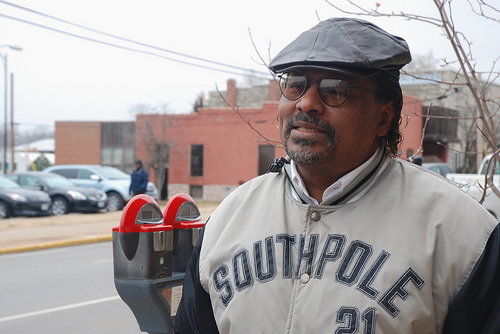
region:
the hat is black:
[265, 13, 416, 80]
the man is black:
[259, 21, 404, 186]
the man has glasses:
[271, 53, 401, 126]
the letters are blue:
[204, 220, 446, 322]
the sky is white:
[56, 53, 143, 100]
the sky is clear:
[52, 53, 140, 105]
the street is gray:
[21, 261, 88, 297]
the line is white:
[22, 277, 98, 324]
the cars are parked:
[22, 144, 94, 236]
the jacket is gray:
[165, 117, 492, 327]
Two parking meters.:
[95, 175, 235, 330]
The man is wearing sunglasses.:
[270, 60, 365, 110]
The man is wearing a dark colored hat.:
[260, 15, 410, 205]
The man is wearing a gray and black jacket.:
[171, 6, 496, 322]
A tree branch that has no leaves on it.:
[405, 5, 495, 176]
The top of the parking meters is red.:
[110, 180, 205, 230]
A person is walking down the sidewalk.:
[120, 147, 150, 202]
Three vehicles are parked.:
[0, 141, 151, 216]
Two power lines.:
[20, 5, 245, 85]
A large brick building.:
[33, 88, 425, 202]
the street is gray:
[27, 264, 100, 284]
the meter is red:
[100, 160, 205, 268]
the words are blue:
[190, 197, 432, 324]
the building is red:
[132, 74, 246, 197]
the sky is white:
[34, 11, 190, 113]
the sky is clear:
[89, 17, 190, 93]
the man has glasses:
[270, 31, 396, 206]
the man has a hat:
[263, 1, 417, 232]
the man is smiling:
[257, 15, 416, 185]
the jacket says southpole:
[182, 195, 452, 329]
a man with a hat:
[256, 16, 399, 206]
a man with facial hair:
[278, 30, 393, 198]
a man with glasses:
[272, 32, 406, 162]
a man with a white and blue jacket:
[267, 27, 440, 327]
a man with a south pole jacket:
[205, 47, 442, 328]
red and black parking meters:
[91, 177, 240, 292]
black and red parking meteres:
[90, 192, 231, 328]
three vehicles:
[0, 152, 175, 211]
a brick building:
[61, 84, 431, 211]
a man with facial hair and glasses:
[254, 35, 431, 196]